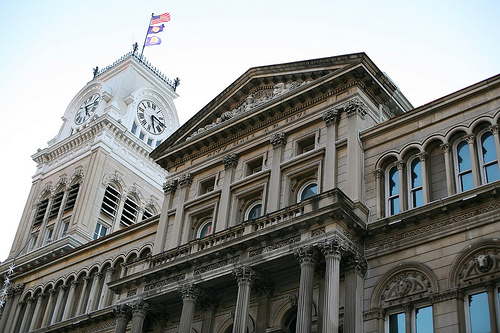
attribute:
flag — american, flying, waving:
[150, 10, 171, 25]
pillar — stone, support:
[229, 264, 250, 333]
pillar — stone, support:
[294, 252, 321, 332]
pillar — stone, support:
[322, 253, 345, 333]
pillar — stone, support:
[178, 292, 198, 332]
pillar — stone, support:
[129, 304, 143, 332]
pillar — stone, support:
[110, 304, 126, 332]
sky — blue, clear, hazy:
[1, 0, 499, 261]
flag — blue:
[149, 24, 166, 32]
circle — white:
[150, 24, 162, 35]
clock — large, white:
[134, 93, 167, 136]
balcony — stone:
[105, 195, 366, 310]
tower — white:
[7, 39, 178, 237]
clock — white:
[70, 94, 99, 126]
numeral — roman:
[152, 101, 156, 111]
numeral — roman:
[144, 100, 154, 110]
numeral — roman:
[141, 103, 142, 109]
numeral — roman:
[152, 122, 158, 135]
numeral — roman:
[141, 116, 148, 131]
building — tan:
[36, 50, 497, 325]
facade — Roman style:
[170, 48, 390, 134]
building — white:
[10, 54, 178, 258]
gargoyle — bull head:
[376, 263, 463, 305]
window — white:
[90, 181, 175, 236]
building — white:
[36, 28, 184, 261]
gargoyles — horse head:
[379, 263, 436, 308]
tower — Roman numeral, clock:
[11, 20, 489, 302]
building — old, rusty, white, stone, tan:
[4, 42, 485, 318]